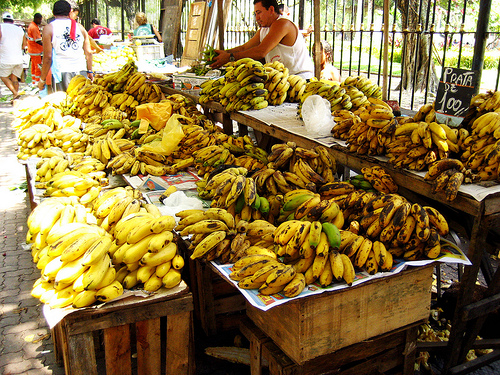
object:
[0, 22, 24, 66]
shirt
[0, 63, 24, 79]
pants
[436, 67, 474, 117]
sign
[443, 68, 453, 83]
letter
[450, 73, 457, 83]
letter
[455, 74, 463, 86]
letter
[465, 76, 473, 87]
letter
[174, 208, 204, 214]
banana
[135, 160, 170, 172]
banana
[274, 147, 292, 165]
banana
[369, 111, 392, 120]
banana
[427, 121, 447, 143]
banana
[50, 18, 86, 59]
back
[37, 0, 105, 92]
man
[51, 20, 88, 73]
tank top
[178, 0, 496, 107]
fence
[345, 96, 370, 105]
banana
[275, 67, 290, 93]
banana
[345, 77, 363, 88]
banana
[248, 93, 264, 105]
banana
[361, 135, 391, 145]
banana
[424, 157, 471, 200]
bananas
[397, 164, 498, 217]
table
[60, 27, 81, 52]
sign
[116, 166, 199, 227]
tables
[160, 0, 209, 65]
wall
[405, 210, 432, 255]
bananas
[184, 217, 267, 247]
fruit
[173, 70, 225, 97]
box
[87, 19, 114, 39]
man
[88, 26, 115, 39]
shirt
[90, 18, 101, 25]
hat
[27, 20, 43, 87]
clothes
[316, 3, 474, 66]
poles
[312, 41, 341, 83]
girl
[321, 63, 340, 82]
shirt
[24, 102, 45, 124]
bananas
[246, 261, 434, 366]
crate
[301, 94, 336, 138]
bag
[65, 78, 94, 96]
bananas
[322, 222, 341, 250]
green banana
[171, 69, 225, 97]
cardboard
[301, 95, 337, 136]
plastic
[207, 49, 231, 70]
hands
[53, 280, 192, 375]
crate boards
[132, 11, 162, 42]
woman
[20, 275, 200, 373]
table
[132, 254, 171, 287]
bananas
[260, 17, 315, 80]
shirt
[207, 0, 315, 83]
man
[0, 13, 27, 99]
man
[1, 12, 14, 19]
white cap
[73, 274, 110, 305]
bananas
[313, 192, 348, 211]
skin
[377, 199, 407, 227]
skin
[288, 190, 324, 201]
skin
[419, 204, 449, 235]
skin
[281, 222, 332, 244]
skin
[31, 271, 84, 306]
plantain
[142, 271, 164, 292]
plantain